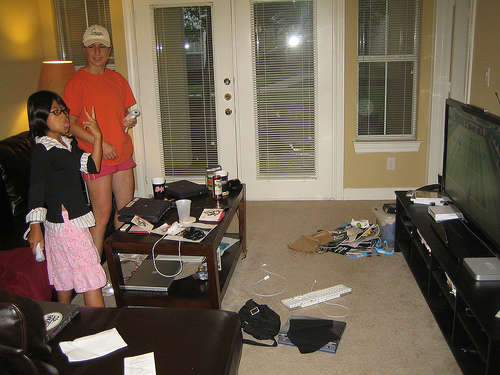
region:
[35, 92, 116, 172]
girl sticks her tongue out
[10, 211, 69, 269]
girl is holding a wii remote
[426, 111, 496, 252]
playing tennis on the wii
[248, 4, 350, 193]
blinds in the door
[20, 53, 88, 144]
the light in the corner is on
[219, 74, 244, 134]
locks on the door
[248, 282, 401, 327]
white keypad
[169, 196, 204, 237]
a cup on the table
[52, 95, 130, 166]
girl is holding up two fingers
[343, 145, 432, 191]
the wall is tan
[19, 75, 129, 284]
A girl blowing bubbles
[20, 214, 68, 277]
A Wii controller in a girl's hand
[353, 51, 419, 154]
Blinds in a window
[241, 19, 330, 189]
A window in a door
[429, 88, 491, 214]
A Wii tennis match shown on a television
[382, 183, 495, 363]
A brown wood tv table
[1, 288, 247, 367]
A brown leather couch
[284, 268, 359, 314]
A keyboard on the floor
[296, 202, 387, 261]
A pile of junk on the floor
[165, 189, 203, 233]
A cup on a table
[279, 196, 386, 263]
woven bags lain out on floor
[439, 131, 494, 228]
large flatscreen tv and white game system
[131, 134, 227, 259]
unkempt living room coffee table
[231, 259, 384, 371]
a keyboard and charger on floor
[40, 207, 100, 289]
pink skirt on younger girl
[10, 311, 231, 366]
dark brown couch in photo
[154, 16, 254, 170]
white paneled door in photo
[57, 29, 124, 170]
lady in orange shirt and tan hat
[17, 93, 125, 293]
girl posing in a funny pose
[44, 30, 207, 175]
lady looking at child in photo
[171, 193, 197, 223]
plastic cup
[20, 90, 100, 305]
a girl in a pink skirt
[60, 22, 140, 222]
girl in an orange t-shirt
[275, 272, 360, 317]
a computer keyboard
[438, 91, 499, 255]
a television set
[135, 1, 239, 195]
a white trimmed door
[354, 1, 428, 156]
a white trimmed window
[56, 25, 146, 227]
a girl wearing a baseball cap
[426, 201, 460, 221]
Nintendo wii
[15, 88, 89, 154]
girl with straight dark hair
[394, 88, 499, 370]
A entertainment center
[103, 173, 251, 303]
a wooden coffee table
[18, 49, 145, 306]
two people holding wii remotes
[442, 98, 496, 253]
a widescreen tv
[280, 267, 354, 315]
a computer keyboard on the floor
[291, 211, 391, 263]
a pile of junk on the floor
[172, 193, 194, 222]
a plastic drinking cup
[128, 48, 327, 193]
a set of french doors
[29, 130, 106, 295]
a pink skirt and a black top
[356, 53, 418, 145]
a window in the living room